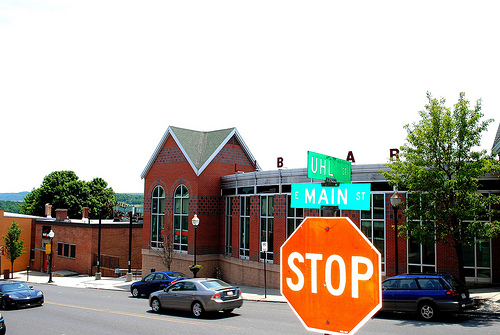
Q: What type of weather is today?
A: It is clear.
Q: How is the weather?
A: It is clear.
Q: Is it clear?
A: Yes, it is clear.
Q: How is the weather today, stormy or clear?
A: It is clear.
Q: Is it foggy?
A: No, it is clear.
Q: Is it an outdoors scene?
A: Yes, it is outdoors.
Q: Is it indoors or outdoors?
A: It is outdoors.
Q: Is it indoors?
A: No, it is outdoors.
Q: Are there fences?
A: No, there are no fences.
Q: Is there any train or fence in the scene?
A: No, there are no fences or trains.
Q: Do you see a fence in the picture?
A: No, there are no fences.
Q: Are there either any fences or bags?
A: No, there are no fences or bags.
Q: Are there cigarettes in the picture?
A: No, there are no cigarettes.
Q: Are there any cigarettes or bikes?
A: No, there are no cigarettes or bikes.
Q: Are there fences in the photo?
A: No, there are no fences.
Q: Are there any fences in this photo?
A: No, there are no fences.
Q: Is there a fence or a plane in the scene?
A: No, there are no fences or airplanes.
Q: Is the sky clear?
A: Yes, the sky is clear.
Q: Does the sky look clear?
A: Yes, the sky is clear.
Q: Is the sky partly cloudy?
A: No, the sky is clear.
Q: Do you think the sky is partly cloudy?
A: No, the sky is clear.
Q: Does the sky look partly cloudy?
A: No, the sky is clear.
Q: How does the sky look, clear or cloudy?
A: The sky is clear.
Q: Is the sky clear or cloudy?
A: The sky is clear.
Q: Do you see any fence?
A: No, there are no fences.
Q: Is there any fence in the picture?
A: No, there are no fences.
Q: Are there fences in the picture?
A: No, there are no fences.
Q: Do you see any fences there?
A: No, there are no fences.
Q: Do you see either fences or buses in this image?
A: No, there are no fences or buses.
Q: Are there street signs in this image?
A: Yes, there is a street sign.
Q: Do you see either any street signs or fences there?
A: Yes, there is a street sign.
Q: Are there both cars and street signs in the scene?
A: Yes, there are both a street sign and a car.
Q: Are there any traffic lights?
A: No, there are no traffic lights.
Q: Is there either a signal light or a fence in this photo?
A: No, there are no traffic lights or fences.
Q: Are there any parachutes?
A: No, there are no parachutes.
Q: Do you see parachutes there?
A: No, there are no parachutes.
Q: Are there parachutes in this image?
A: No, there are no parachutes.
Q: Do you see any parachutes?
A: No, there are no parachutes.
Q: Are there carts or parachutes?
A: No, there are no parachutes or carts.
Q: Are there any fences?
A: No, there are no fences.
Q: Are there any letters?
A: Yes, there are letters.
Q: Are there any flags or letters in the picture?
A: Yes, there are letters.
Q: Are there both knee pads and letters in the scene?
A: No, there are letters but no knee pads.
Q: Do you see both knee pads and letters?
A: No, there are letters but no knee pads.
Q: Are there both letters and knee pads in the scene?
A: No, there are letters but no knee pads.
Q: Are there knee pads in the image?
A: No, there are no knee pads.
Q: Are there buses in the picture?
A: No, there are no buses.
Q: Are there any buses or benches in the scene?
A: No, there are no buses or benches.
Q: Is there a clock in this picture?
A: No, there are no clocks.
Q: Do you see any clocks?
A: No, there are no clocks.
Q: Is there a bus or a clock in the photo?
A: No, there are no clocks or buses.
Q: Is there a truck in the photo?
A: No, there are no trucks.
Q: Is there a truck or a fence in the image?
A: No, there are no trucks or fences.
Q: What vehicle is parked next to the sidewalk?
A: The vehicle is a car.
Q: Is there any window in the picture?
A: Yes, there is a window.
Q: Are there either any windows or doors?
A: Yes, there is a window.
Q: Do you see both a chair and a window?
A: No, there is a window but no chairs.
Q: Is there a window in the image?
A: Yes, there is a window.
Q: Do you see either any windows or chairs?
A: Yes, there is a window.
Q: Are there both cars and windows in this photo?
A: Yes, there are both a window and a car.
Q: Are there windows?
A: Yes, there is a window.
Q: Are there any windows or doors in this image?
A: Yes, there is a window.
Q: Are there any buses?
A: No, there are no buses.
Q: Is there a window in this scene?
A: Yes, there is a window.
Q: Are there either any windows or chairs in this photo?
A: Yes, there is a window.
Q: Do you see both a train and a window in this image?
A: No, there is a window but no trains.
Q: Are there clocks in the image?
A: No, there are no clocks.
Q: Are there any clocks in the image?
A: No, there are no clocks.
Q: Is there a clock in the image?
A: No, there are no clocks.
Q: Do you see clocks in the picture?
A: No, there are no clocks.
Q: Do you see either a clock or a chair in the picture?
A: No, there are no clocks or chairs.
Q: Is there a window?
A: Yes, there is a window.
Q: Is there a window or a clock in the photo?
A: Yes, there is a window.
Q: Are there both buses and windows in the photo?
A: No, there is a window but no buses.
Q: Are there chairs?
A: No, there are no chairs.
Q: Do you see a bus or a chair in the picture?
A: No, there are no chairs or buses.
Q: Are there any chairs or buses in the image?
A: No, there are no chairs or buses.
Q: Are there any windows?
A: Yes, there is a window.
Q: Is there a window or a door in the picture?
A: Yes, there is a window.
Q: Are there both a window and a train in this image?
A: No, there is a window but no trains.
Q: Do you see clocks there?
A: No, there are no clocks.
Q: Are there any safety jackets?
A: No, there are no safety jackets.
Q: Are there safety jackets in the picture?
A: No, there are no safety jackets.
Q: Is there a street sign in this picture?
A: Yes, there is a street sign.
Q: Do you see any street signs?
A: Yes, there is a street sign.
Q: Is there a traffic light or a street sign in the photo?
A: Yes, there is a street sign.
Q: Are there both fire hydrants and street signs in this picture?
A: No, there is a street sign but no fire hydrants.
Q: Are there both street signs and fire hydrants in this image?
A: No, there is a street sign but no fire hydrants.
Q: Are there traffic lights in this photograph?
A: No, there are no traffic lights.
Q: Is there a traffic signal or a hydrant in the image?
A: No, there are no traffic lights or fire hydrants.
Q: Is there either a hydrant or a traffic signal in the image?
A: No, there are no traffic lights or fire hydrants.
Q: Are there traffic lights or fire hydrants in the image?
A: No, there are no traffic lights or fire hydrants.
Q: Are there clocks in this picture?
A: No, there are no clocks.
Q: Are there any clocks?
A: No, there are no clocks.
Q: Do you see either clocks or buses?
A: No, there are no clocks or buses.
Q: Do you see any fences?
A: No, there are no fences.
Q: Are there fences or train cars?
A: No, there are no fences or train cars.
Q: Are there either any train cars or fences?
A: No, there are no fences or train cars.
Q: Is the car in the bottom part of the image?
A: Yes, the car is in the bottom of the image.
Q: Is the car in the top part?
A: No, the car is in the bottom of the image.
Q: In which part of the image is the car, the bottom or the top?
A: The car is in the bottom of the image.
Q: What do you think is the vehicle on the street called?
A: The vehicle is a car.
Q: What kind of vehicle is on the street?
A: The vehicle is a car.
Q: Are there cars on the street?
A: Yes, there is a car on the street.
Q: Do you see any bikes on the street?
A: No, there is a car on the street.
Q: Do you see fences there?
A: No, there are no fences.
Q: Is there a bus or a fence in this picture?
A: No, there are no fences or buses.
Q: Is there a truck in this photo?
A: No, there are no trucks.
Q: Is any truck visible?
A: No, there are no trucks.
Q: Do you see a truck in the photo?
A: No, there are no trucks.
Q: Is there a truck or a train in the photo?
A: No, there are no trucks or trains.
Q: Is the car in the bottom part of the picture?
A: Yes, the car is in the bottom of the image.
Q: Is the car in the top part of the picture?
A: No, the car is in the bottom of the image.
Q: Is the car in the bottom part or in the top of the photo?
A: The car is in the bottom of the image.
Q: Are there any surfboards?
A: No, there are no surfboards.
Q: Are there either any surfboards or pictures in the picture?
A: No, there are no surfboards or pictures.